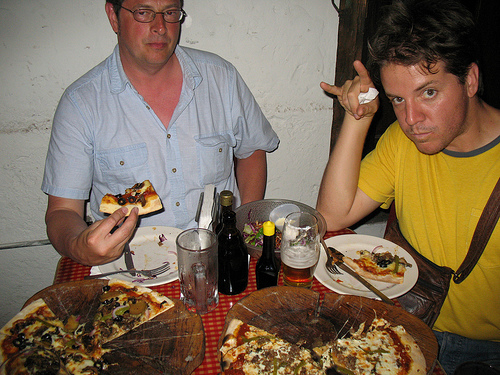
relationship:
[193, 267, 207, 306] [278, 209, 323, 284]
handle on glass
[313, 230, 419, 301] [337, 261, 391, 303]
plate with knife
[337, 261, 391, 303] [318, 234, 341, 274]
knife with fork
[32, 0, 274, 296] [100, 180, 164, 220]
man eating pizza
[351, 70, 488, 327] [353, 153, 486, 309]
man in shirt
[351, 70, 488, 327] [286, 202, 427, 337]
man eating pizza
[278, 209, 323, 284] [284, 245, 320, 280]
glass of beer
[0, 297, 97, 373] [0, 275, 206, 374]
pizza on wooden tray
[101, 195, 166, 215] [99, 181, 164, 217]
crust on pizza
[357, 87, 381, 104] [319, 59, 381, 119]
napkin in hand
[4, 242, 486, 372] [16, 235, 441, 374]
table cloth on table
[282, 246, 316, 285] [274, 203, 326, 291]
beer in glass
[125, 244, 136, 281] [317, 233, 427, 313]
knife on plate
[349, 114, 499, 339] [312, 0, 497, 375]
shirt on man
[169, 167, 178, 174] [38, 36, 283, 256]
button on shirt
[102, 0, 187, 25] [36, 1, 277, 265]
glasses on man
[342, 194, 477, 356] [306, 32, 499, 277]
bag with man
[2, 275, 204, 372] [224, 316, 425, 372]
wooden tray on pizza